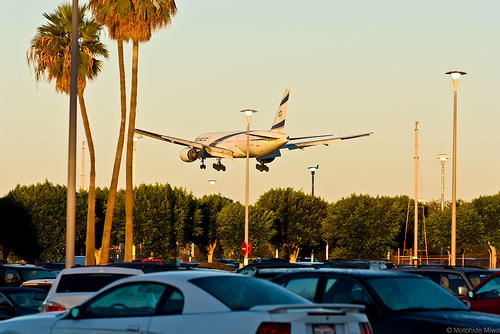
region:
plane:
[110, 91, 344, 181]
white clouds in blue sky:
[382, 11, 430, 43]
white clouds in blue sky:
[358, 52, 393, 94]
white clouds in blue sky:
[214, 39, 255, 61]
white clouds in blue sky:
[340, 68, 410, 109]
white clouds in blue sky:
[352, 129, 399, 160]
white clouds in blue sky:
[18, 118, 52, 150]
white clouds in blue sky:
[182, 22, 257, 56]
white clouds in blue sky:
[162, 39, 212, 87]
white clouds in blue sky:
[307, 23, 377, 67]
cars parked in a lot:
[129, 268, 470, 324]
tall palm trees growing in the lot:
[44, 5, 147, 291]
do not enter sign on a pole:
[239, 237, 249, 256]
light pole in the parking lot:
[444, 65, 461, 270]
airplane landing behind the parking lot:
[146, 116, 354, 164]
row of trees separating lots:
[22, 185, 418, 256]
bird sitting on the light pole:
[313, 160, 324, 168]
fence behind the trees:
[396, 246, 476, 262]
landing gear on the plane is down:
[199, 160, 275, 174]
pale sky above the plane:
[182, 17, 352, 74]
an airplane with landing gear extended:
[127, 87, 374, 172]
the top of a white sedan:
[0, 265, 372, 332]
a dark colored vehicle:
[270, 263, 499, 332]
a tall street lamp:
[444, 66, 468, 264]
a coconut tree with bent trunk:
[26, 2, 109, 268]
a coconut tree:
[85, 0, 180, 263]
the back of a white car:
[37, 263, 144, 317]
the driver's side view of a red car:
[455, 266, 498, 313]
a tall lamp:
[238, 105, 258, 264]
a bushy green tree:
[213, 198, 278, 265]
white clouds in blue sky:
[411, 31, 451, 65]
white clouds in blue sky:
[341, 86, 432, 150]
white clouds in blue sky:
[168, 49, 233, 123]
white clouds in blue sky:
[284, 23, 335, 50]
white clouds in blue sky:
[392, 9, 469, 64]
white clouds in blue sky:
[294, 36, 365, 71]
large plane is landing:
[139, 79, 327, 186]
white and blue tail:
[259, 76, 296, 137]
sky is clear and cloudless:
[308, 24, 420, 142]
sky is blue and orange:
[341, 36, 434, 191]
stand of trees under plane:
[9, 181, 472, 253]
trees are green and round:
[14, 169, 495, 257]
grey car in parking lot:
[26, 261, 336, 330]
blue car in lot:
[276, 259, 475, 332]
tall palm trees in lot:
[33, 8, 193, 290]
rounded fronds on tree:
[44, 1, 170, 126]